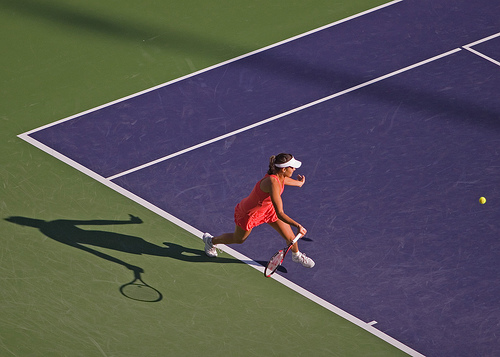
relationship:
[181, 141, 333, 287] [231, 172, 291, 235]
woman wearing dress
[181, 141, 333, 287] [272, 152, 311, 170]
woman wearing sun visor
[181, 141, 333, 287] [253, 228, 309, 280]
woman holding racket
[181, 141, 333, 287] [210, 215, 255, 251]
woman has a leg